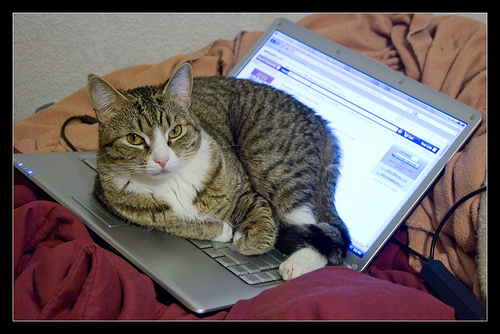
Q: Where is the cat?
A: On the laptop.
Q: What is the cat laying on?
A: A laptop.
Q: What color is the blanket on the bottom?
A: Red.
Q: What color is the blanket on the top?
A: Tan.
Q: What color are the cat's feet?
A: White.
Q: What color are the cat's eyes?
A: Brown.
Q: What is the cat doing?
A: Laying on a laptop.